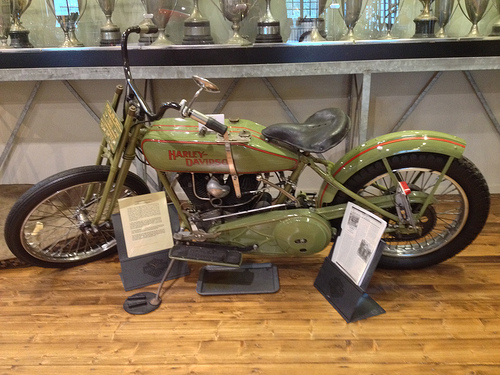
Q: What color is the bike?
A: Green.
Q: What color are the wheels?
A: Black.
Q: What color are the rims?
A: Gray.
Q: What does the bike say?
A: Harley Davidson.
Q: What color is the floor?
A: Brown.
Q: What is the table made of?
A: Metal.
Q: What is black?
A: The seat.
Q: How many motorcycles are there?
A: One.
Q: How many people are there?
A: None.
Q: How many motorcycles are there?
A: One.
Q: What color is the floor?
A: Brown.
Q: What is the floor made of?
A: Wood.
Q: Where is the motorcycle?
A: On the floor.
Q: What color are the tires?
A: Black.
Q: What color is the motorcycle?
A: Green.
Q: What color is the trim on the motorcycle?
A: Red.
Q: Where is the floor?
A: Under the motorcycle.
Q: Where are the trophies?
A: On the shelf.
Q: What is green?
A: Motorcycle.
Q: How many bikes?
A: One.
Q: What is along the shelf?
A: Trophies.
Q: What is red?
A: Trim.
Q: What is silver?
A: Spokes.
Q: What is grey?
A: Pan under bike.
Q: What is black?
A: Tires.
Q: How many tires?
A: Two.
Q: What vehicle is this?
A: Motorbike.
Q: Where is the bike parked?
A: Indoors on a display.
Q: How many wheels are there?
A: Two.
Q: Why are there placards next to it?
A: It is on display at museum.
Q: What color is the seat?
A: Black.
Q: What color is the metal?
A: Light green.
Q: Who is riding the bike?
A: No one.